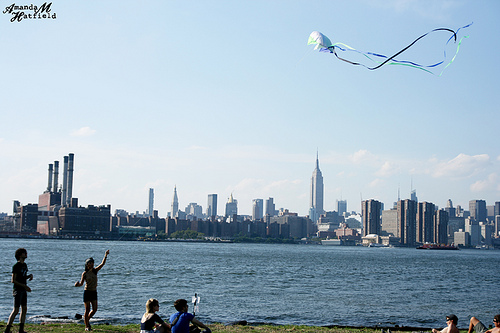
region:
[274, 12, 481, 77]
a kite is in the sky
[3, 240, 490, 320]
the ocean is blue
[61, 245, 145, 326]
the woman is pointing at the kite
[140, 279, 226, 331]
the kids are watching the kite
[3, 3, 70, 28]
amanda m hatfield took this picture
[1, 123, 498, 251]
buildings are on the other side of the river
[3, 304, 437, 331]
the grass is green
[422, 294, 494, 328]
the people are laying on the grass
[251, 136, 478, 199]
clouds are in the sky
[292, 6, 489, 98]
the wind is blowing the kite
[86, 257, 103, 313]
a lady pointing to something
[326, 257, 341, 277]
part of ocean water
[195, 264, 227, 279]
part of sea water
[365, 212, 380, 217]
part of a building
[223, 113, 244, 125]
part of a cloud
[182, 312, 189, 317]
back of a man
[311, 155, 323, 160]
tip of a building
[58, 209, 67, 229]
edge of a building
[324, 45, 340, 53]
a white kite in air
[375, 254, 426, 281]
ripples of ocean water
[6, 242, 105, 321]
Two people running on grass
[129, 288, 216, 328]
Two people sitting on grass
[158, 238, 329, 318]
Water next to a park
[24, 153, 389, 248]
Buildings in a city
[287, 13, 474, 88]
Kite in the sky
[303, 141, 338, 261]
Skyscraper in a city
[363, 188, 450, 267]
Tall buildings in a city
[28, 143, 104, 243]
Smoke stacks on a building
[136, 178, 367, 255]
Several tall buildings in a city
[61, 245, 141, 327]
Woman holding up her hand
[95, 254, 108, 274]
the arm of the woman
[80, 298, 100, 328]
the legs of the woman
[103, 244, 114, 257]
the hand of the woman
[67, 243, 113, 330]
a woman on the shore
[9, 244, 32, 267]
the head of the man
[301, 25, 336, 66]
a kite in the sky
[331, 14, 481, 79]
streamers behind the kite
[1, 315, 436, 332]
a green grassy shore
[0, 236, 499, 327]
a blue body of water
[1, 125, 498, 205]
clouds in the sky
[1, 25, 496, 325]
Buildings are near the water.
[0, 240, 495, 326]
People are sitting near water.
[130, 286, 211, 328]
Two people sitting down.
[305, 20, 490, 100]
A kite in the sky.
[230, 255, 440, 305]
The water has ripples.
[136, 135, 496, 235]
Buildings along the horizon.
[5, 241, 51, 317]
A person standing up.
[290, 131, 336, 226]
A tall pointy building.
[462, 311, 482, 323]
A person's knee.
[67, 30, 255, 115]
The blue sky.